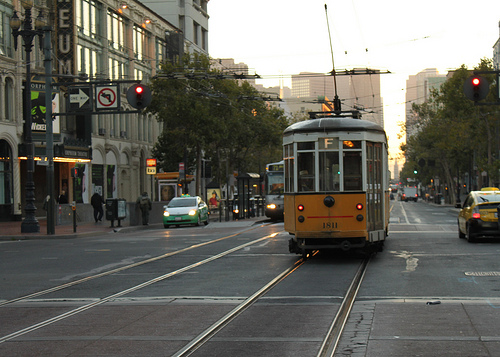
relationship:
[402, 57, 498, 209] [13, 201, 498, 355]
trees growing next to road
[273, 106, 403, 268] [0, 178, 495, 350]
trolley in street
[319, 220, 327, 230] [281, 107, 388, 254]
number in front of trolley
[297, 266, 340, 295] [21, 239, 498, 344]
surface of street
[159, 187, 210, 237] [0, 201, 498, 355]
cab on side of road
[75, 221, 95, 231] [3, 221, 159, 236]
surface of sidewalk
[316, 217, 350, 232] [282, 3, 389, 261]
number on front of trolley